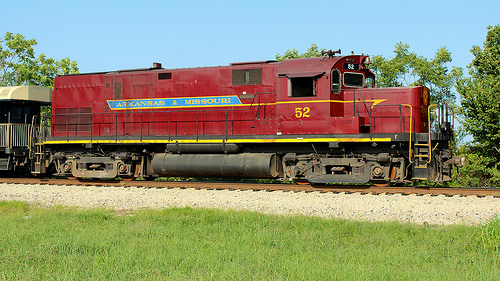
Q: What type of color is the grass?
A: Green.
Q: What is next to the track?
A: Dirt.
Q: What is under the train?
A: Track.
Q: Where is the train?
A: On the tracks.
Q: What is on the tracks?
A: A train.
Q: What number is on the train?
A: 52.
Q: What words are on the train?
A: Arkansas & missouri.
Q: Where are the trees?
A: Behind the train.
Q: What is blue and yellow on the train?
A: The sign with writing.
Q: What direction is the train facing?
A: Right.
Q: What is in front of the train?
A: Grassy field.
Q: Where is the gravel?
A: On the sides of the tracks.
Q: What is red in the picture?
A: The train.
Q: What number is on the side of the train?
A: 52.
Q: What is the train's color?
A: Red.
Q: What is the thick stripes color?
A: Blue.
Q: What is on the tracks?
A: A train.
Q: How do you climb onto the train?
A: With the ladder.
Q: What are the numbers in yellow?
A: 52.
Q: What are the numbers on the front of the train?
A: 52.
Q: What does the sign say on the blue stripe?
A: Arkansas & Missouri.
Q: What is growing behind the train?
A: Trees.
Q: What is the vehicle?
A: Train.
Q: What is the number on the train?
A: 52.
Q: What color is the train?
A: Red.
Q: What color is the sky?
A: Blue.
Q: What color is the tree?
A: Green.